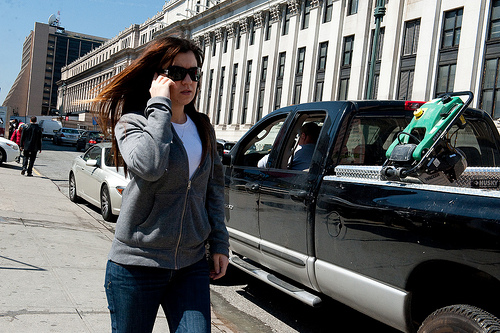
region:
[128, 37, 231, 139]
the head of a woman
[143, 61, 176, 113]
the hand of a woman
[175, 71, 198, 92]
the nose of a woman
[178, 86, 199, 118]
the mouth of a woman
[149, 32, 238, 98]
a woman wearing sunglasses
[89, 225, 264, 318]
a woman wearing jeans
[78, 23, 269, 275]
a woman wearing a hoody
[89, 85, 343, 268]
a woman near a truck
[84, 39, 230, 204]
the arm of a woman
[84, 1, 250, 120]
the hair of a woman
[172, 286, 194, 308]
part of a thigh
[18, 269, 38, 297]
part of a floor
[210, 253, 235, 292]
part of a hand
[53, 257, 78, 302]
part of a line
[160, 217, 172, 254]
part of a pocket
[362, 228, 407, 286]
part of a trunk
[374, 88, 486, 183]
the electric equpiment in the bed of the truck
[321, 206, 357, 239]
the round door to the gas tank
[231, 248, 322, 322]
the step to the truck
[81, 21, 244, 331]
the women walking on the sidewalk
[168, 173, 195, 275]
the sipper on the persons jacket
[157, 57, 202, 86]
the sunglasses on the womens face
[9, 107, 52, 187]
the people walking on the sidewalk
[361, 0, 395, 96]
the light post on the sidewalk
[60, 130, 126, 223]
the car parked on the roadside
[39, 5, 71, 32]
the dish on top of the building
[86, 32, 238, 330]
a woman walking down the sidewalk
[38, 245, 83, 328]
grey concrete surface of the sidewalk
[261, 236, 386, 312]
grey trim of the blue truck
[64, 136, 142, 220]
a grey car parked in the street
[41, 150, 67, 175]
black asphalt surface of the road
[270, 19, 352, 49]
white stone wall of the building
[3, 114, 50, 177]
several people walking on the sidewalk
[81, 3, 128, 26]
clear blue skies over the buildings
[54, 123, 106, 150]
two cars driving in the street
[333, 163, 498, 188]
grey metal box in the bed of the truck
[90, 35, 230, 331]
A women walking along a sidewalk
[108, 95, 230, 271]
A partially zipped up grey sweater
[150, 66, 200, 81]
Large black sunglasses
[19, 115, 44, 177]
A person in dark clothing walking on a sidewalk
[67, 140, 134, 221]
A grey two door car parked on the side of a road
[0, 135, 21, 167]
The front of a white car blocking part of the sidewalk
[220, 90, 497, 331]
Dark four door truck with tools in the bed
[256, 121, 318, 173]
Person sitting in a dark two tone truck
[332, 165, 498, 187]
Metal box in the back of a truck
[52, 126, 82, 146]
Silver car in traffic